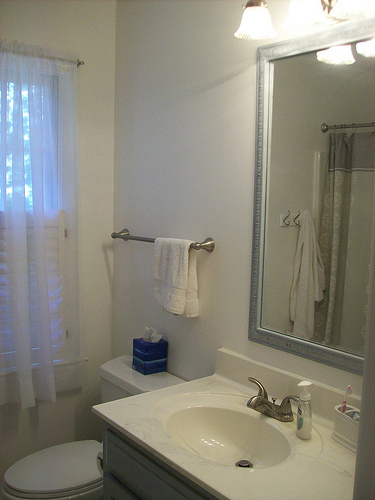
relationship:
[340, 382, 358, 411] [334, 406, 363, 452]
toothbrush in holder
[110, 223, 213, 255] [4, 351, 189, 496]
bar above commode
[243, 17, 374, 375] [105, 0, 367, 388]
mirror on wall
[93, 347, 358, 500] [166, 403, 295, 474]
sink has basin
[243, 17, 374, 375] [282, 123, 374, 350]
mirror has reflection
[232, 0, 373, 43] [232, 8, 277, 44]
lighting has shade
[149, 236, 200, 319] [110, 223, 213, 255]
towel on bar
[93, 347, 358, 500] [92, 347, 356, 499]
sink in countertop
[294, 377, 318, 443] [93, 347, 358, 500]
soap by sink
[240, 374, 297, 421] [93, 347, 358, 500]
faucet on sink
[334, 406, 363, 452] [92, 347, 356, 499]
holder on countertop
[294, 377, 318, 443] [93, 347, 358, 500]
soap on sink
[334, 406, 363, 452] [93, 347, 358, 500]
holder on sink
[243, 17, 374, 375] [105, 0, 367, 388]
mirror affixed to wall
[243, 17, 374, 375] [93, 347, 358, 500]
mirror above sink